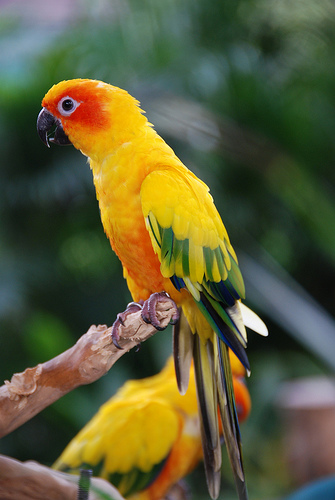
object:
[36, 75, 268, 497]
bird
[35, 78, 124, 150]
head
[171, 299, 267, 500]
tail feather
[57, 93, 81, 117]
eye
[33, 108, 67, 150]
beak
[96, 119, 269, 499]
feather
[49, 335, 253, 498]
bird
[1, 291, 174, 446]
perch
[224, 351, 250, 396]
face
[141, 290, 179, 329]
foot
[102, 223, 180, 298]
belly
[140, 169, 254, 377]
wing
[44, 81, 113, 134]
patch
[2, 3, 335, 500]
tree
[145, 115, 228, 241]
back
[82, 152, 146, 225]
breast